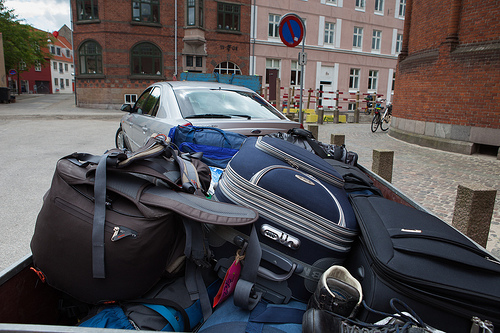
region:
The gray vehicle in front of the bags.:
[112, 77, 312, 149]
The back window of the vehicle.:
[172, 86, 274, 121]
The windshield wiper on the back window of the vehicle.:
[189, 106, 262, 123]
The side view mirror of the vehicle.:
[117, 97, 135, 116]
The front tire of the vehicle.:
[111, 118, 132, 148]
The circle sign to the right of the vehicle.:
[269, 11, 311, 53]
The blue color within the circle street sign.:
[284, 16, 304, 42]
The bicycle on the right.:
[362, 91, 400, 136]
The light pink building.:
[257, 0, 390, 120]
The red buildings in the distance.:
[5, 18, 74, 93]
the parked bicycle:
[368, 100, 392, 139]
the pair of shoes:
[302, 262, 424, 332]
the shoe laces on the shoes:
[329, 298, 424, 332]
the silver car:
[113, 78, 304, 153]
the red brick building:
[388, 1, 498, 149]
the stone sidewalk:
[312, 106, 498, 243]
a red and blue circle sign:
[278, 18, 303, 48]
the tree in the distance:
[0, 1, 55, 76]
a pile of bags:
[10, 124, 499, 331]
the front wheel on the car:
[112, 125, 127, 152]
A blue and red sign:
[276, 13, 305, 48]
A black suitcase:
[350, 195, 499, 332]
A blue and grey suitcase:
[211, 136, 358, 308]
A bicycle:
[370, 104, 390, 131]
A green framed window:
[127, 40, 164, 78]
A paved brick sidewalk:
[301, 120, 496, 252]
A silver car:
[115, 81, 302, 146]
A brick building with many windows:
[70, 0, 247, 106]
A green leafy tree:
[0, 10, 46, 70]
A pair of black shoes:
[302, 263, 429, 331]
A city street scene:
[6, 5, 491, 326]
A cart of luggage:
[0, 118, 497, 331]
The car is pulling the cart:
[4, 74, 497, 331]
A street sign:
[276, 11, 311, 122]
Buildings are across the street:
[2, 0, 393, 106]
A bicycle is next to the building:
[366, 97, 407, 134]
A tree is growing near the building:
[2, 0, 71, 100]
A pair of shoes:
[300, 262, 450, 331]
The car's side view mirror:
[118, 101, 138, 116]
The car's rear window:
[171, 84, 288, 119]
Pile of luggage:
[60, 135, 445, 325]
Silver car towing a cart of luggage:
[115, 80, 425, 325]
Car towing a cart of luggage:
[0, 60, 465, 320]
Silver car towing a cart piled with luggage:
[0, 85, 485, 330]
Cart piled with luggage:
[0, 135, 430, 325]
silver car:
[95, 75, 315, 180]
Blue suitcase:
[225, 115, 360, 285]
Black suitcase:
[350, 190, 490, 310]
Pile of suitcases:
[85, 130, 441, 330]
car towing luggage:
[16, 84, 483, 329]